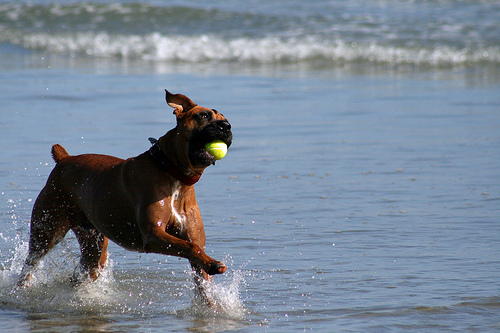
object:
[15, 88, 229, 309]
dog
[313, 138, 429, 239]
water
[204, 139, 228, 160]
ball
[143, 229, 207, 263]
leg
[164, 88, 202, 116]
ear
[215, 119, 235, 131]
nose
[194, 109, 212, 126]
eye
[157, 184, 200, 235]
chest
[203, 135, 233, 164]
mouth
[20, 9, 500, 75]
waves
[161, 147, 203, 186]
collar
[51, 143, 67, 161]
tail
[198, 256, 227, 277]
foot